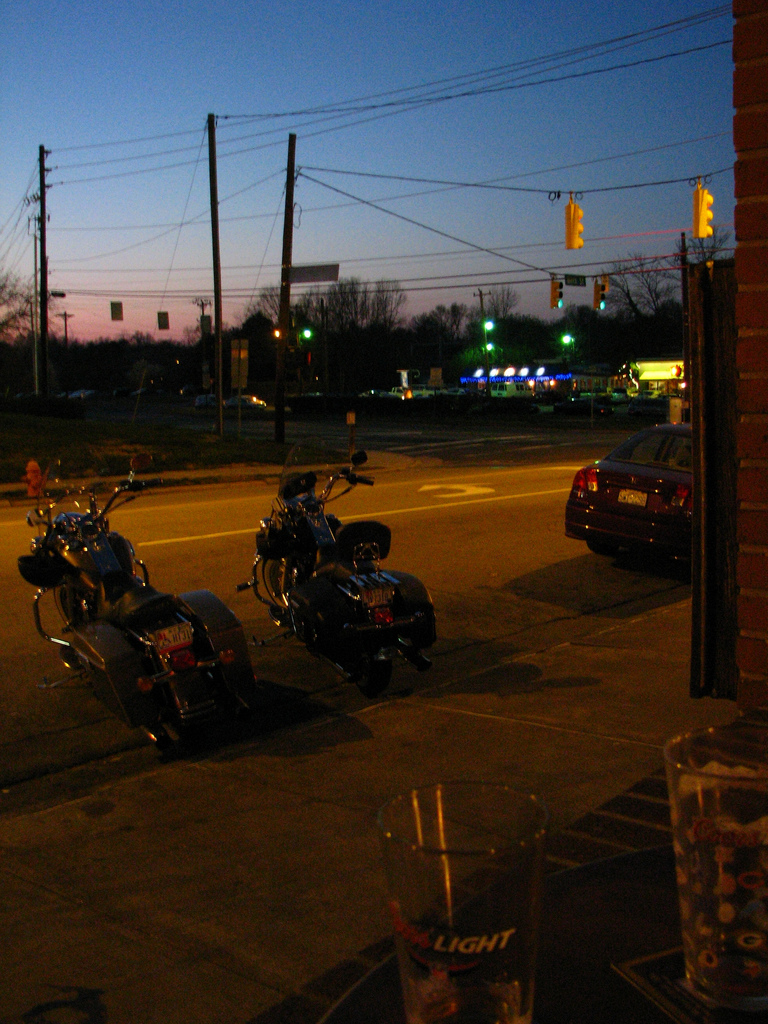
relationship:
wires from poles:
[4, 5, 765, 317] [24, 240, 262, 414]